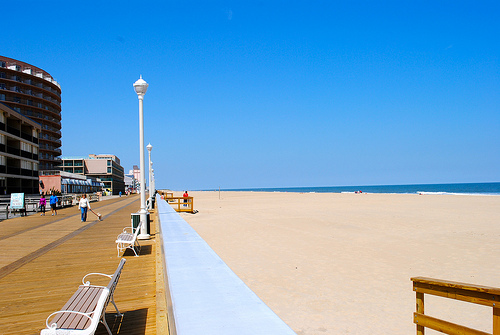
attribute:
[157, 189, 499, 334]
sand — Brown , clean, neat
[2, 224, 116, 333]
deck — golden brown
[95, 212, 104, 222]
dog — small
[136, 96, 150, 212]
post — tall, white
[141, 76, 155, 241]
lightpost — white, tall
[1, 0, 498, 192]
blue sky — clear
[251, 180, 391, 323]
sand — Brown 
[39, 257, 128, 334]
bench — white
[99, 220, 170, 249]
bench — white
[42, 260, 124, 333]
bench — white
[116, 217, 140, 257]
bench — white